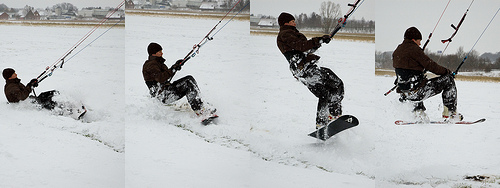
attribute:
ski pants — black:
[290, 64, 352, 119]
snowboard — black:
[297, 109, 374, 155]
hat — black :
[272, 12, 294, 23]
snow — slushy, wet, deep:
[125, 106, 262, 186]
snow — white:
[218, 88, 300, 173]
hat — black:
[144, 41, 162, 54]